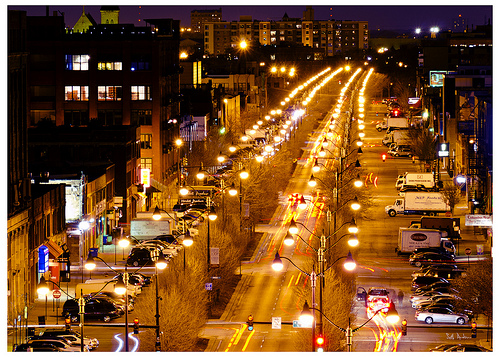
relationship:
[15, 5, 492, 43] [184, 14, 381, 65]
sky above building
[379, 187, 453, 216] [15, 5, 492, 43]
truck below sky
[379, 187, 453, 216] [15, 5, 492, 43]
truck under sky